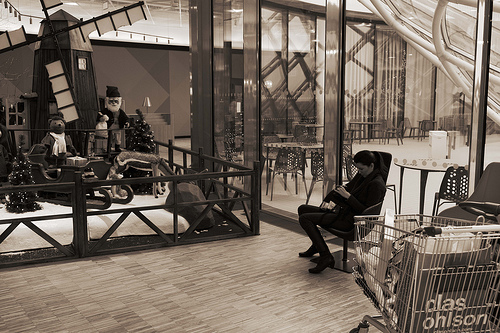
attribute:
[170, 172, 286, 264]
design — black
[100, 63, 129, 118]
hat — large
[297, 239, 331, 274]
boots — black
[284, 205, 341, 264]
pants — skinny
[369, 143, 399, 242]
chair — black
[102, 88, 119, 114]
beard — white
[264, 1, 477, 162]
glass — large, panels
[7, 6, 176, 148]
windmill — large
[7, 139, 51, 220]
tree — small, miniature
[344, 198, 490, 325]
trolley — silver, full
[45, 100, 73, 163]
doll — win powered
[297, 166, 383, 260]
woman — sitting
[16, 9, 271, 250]
decorations — done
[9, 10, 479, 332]
scene — black-and-white, christmas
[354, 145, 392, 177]
hair — ponytail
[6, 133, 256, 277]
fence — wooden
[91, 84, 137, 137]
santa — life-size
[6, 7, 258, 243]
display — christmas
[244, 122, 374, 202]
chairs — enclosed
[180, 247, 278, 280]
line — black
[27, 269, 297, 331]
floor — wooden